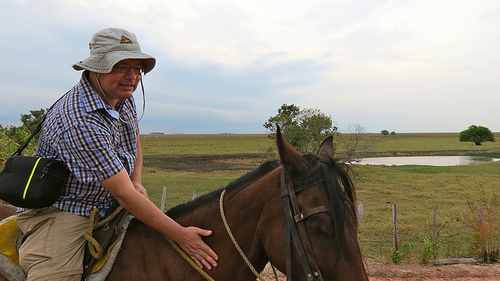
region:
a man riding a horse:
[19, 25, 396, 269]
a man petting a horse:
[12, 17, 377, 265]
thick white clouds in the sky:
[280, 14, 477, 91]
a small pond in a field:
[360, 147, 497, 165]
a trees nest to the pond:
[451, 120, 493, 151]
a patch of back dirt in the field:
[151, 145, 258, 170]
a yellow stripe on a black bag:
[24, 160, 34, 200]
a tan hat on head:
[73, 20, 159, 65]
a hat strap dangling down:
[142, 87, 146, 120]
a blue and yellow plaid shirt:
[39, 92, 145, 204]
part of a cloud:
[245, 44, 279, 92]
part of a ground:
[421, 156, 448, 185]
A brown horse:
[2, 120, 369, 279]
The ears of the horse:
[269, 121, 339, 163]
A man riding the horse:
[19, 16, 221, 276]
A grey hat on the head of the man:
[71, 20, 159, 77]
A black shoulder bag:
[3, 89, 71, 208]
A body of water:
[352, 148, 498, 168]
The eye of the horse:
[303, 216, 330, 241]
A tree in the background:
[457, 125, 497, 147]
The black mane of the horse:
[156, 153, 280, 217]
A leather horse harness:
[275, 163, 335, 278]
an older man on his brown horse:
[0, 27, 368, 279]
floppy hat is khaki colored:
[72, 27, 157, 74]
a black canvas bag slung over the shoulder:
[1, 88, 136, 210]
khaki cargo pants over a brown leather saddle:
[13, 205, 125, 280]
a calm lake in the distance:
[342, 153, 498, 166]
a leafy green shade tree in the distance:
[460, 125, 495, 145]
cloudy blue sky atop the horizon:
[0, 0, 499, 135]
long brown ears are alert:
[275, 125, 334, 179]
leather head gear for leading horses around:
[279, 165, 354, 280]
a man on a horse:
[7, 14, 409, 277]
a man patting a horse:
[8, 12, 365, 279]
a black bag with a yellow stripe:
[0, 72, 70, 207]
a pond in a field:
[351, 140, 496, 175]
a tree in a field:
[448, 121, 495, 157]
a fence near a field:
[360, 193, 468, 273]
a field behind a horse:
[170, 129, 499, 246]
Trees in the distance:
[373, 110, 405, 145]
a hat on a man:
[55, 12, 165, 117]